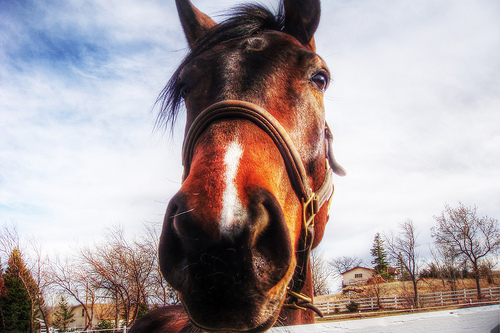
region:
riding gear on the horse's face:
[176, 103, 331, 240]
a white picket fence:
[314, 288, 496, 315]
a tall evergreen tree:
[368, 231, 393, 279]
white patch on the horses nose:
[221, 139, 241, 229]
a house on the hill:
[341, 266, 384, 288]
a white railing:
[273, 307, 499, 331]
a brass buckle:
[302, 195, 320, 220]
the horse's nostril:
[253, 198, 291, 295]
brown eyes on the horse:
[310, 70, 328, 90]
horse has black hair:
[159, 5, 279, 122]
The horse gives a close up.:
[155, 0, 341, 331]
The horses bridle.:
[275, 140, 343, 242]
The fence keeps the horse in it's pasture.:
[327, 318, 497, 329]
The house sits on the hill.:
[335, 264, 401, 288]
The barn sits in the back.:
[67, 297, 138, 327]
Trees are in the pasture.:
[0, 230, 50, 331]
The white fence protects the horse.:
[325, 283, 498, 306]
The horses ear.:
[171, 1, 234, 34]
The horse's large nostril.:
[243, 185, 304, 294]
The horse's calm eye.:
[302, 57, 337, 97]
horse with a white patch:
[204, 133, 253, 233]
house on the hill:
[333, 254, 408, 284]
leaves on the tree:
[368, 235, 391, 297]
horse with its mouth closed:
[159, 273, 304, 329]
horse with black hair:
[156, 1, 276, 83]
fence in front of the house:
[333, 288, 492, 311]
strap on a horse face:
[161, 78, 313, 201]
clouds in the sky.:
[69, 24, 119, 41]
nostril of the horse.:
[257, 225, 282, 280]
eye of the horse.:
[308, 69, 327, 91]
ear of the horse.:
[181, 5, 216, 31]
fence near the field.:
[325, 298, 345, 312]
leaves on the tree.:
[5, 298, 22, 320]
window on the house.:
[350, 270, 363, 280]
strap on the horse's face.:
[251, 113, 300, 160]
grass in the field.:
[387, 285, 394, 293]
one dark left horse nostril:
[246, 184, 292, 293]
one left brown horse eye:
[306, 62, 331, 94]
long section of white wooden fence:
[312, 285, 498, 320]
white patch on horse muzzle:
[216, 136, 244, 236]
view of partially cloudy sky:
[8, 13, 145, 206]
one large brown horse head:
[151, 3, 343, 332]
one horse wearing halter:
[153, 2, 343, 327]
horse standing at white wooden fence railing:
[143, 0, 490, 332]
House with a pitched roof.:
[339, 264, 379, 291]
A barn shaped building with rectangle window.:
[68, 303, 103, 332]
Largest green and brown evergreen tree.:
[0, 249, 45, 332]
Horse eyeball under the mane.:
[181, 86, 192, 99]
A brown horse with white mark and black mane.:
[127, 0, 333, 332]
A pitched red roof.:
[337, 266, 377, 276]